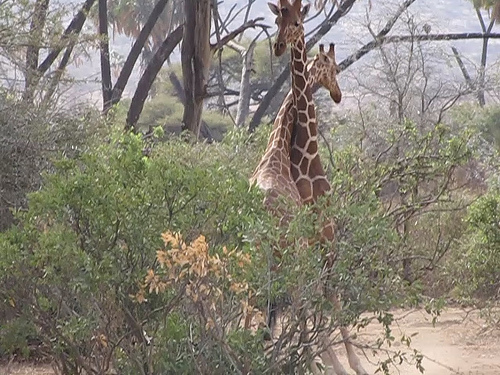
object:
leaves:
[141, 160, 148, 164]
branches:
[55, 328, 76, 350]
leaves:
[198, 175, 202, 179]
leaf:
[398, 119, 422, 139]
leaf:
[152, 124, 167, 140]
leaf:
[471, 205, 481, 221]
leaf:
[123, 187, 148, 205]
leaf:
[93, 258, 120, 272]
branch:
[261, 234, 276, 339]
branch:
[388, 304, 429, 320]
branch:
[378, 167, 456, 223]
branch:
[172, 189, 200, 215]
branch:
[102, 220, 121, 255]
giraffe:
[266, 0, 369, 375]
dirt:
[271, 303, 500, 375]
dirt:
[1, 351, 58, 375]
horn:
[319, 43, 325, 53]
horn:
[329, 42, 335, 53]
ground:
[237, 302, 500, 373]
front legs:
[307, 302, 348, 375]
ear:
[266, 0, 282, 18]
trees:
[447, 0, 500, 107]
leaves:
[180, 254, 195, 260]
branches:
[210, 309, 216, 323]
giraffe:
[247, 41, 345, 375]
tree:
[313, 1, 500, 99]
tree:
[96, 0, 170, 122]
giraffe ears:
[335, 63, 342, 74]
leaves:
[452, 149, 459, 156]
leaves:
[374, 227, 377, 229]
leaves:
[120, 141, 136, 154]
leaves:
[37, 234, 48, 238]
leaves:
[80, 185, 91, 194]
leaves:
[149, 155, 159, 160]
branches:
[376, 210, 399, 224]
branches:
[386, 141, 393, 152]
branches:
[271, 343, 280, 359]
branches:
[156, 305, 170, 325]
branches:
[59, 333, 71, 345]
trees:
[20, 0, 97, 107]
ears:
[318, 51, 332, 66]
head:
[263, 0, 312, 90]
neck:
[289, 33, 325, 180]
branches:
[164, 183, 175, 216]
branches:
[370, 146, 392, 164]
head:
[289, 40, 344, 119]